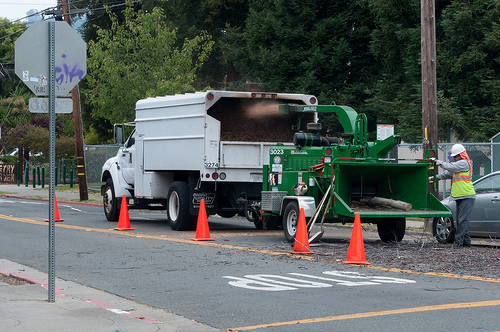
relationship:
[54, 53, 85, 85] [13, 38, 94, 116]
graffiti on sign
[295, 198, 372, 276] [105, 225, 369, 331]
cones on street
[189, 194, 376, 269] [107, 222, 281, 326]
cones on street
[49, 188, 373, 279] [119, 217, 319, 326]
cones on street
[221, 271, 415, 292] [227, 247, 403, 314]
text on street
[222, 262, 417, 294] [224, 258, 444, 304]
stop on text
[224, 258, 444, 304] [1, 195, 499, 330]
text on street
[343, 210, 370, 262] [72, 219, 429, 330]
cone on street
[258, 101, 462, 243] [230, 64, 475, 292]
trailer on truck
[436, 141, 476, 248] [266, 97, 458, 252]
city employee working on chipper truck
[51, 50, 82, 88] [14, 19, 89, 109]
graffiti back of stop sign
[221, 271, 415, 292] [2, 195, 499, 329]
text on road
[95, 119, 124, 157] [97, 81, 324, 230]
mirror on truck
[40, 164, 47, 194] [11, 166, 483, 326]
post sticking out of ground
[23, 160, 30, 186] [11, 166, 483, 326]
post sticking out of ground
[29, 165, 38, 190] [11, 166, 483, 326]
post sticking out of ground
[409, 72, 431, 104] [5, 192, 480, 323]
pole side of road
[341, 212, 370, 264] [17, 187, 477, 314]
cone on ground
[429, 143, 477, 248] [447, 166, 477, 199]
man wearing yellow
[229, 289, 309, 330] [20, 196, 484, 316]
line on ground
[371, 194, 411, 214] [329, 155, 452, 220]
limb back of lifter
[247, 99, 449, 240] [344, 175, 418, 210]
green lifter with tree limbs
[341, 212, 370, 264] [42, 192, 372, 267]
cone in line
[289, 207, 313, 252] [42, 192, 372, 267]
cone in line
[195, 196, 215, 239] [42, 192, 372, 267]
cone in line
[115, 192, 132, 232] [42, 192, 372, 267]
cone in line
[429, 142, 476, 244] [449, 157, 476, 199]
man wearing reflective clothing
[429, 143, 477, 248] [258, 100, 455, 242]
man working on wood chipper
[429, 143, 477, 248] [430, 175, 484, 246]
man front of car